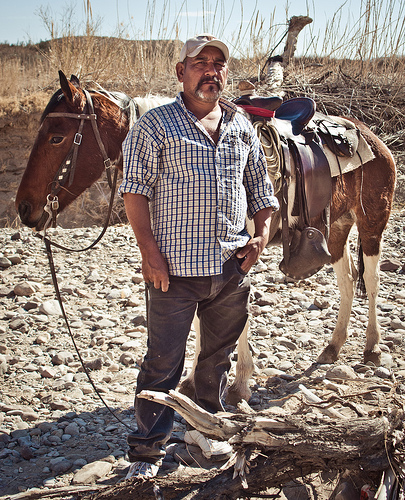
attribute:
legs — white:
[329, 167, 386, 368]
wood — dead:
[1, 388, 403, 498]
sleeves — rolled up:
[84, 137, 208, 220]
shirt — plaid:
[118, 99, 279, 232]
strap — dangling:
[33, 239, 171, 438]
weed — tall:
[294, 33, 384, 121]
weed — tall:
[336, 2, 389, 92]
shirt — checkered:
[120, 89, 282, 285]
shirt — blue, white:
[114, 90, 277, 274]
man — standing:
[114, 23, 263, 268]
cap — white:
[183, 26, 223, 60]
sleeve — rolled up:
[117, 129, 161, 204]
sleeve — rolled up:
[244, 141, 280, 217]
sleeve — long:
[253, 155, 278, 215]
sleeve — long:
[127, 122, 150, 192]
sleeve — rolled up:
[245, 167, 278, 215]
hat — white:
[176, 33, 230, 63]